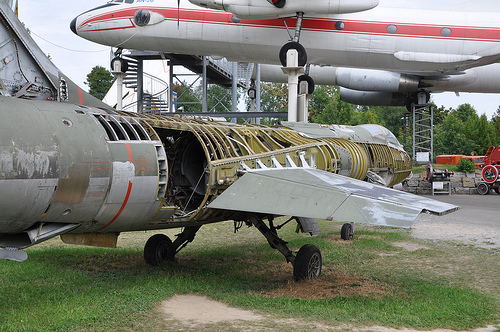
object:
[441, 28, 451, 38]
window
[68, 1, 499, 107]
airplane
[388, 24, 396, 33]
window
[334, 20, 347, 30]
window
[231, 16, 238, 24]
window